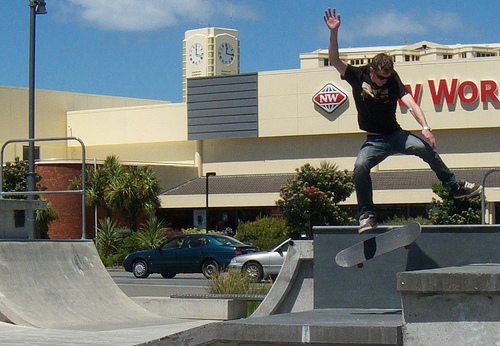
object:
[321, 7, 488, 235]
man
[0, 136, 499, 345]
skate park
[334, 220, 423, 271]
black skateboard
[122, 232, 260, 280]
car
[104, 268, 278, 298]
street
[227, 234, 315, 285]
car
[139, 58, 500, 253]
buildings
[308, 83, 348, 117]
sign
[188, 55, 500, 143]
wall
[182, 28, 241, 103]
tower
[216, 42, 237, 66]
clock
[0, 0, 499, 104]
cloudy blue sky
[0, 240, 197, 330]
half pipe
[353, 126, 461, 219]
jeans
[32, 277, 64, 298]
grey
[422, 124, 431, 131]
silver watch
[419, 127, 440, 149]
man's hand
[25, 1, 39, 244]
tall pole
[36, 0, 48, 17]
light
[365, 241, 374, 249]
black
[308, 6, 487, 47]
cloud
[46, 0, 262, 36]
cloud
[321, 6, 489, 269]
trick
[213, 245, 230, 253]
dark green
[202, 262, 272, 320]
tall grass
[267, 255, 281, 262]
silver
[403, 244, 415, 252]
red wheel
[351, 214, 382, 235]
man's feet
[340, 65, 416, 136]
black shirt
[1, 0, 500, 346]
background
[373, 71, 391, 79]
sunglasses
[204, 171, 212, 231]
pole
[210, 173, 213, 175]
black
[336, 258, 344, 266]
grey